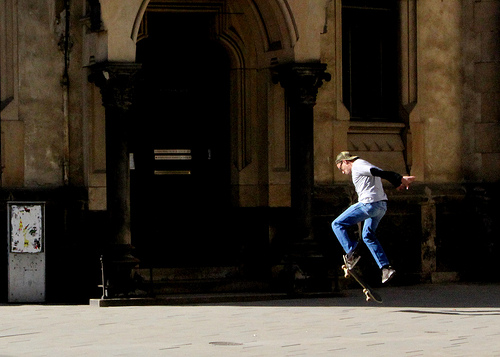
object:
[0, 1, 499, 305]
building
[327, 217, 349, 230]
knee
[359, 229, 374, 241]
knee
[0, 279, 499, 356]
ground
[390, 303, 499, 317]
shadow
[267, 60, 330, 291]
column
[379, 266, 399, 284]
shoe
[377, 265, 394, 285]
foot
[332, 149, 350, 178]
head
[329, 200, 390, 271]
jeans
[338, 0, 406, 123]
window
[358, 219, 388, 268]
leg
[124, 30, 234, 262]
door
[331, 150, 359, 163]
hat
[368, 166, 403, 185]
sleeves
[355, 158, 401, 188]
arm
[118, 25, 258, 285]
doorway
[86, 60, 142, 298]
column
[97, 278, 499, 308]
shadow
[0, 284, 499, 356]
surface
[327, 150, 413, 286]
man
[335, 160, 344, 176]
shades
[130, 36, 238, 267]
entrance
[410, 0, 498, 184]
wall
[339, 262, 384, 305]
skateboard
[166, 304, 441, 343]
air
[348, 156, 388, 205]
shirt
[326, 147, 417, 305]
skate